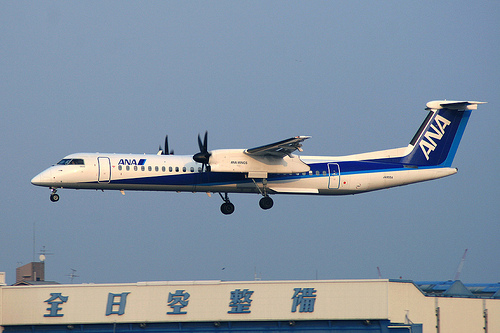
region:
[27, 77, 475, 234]
Large plane flying in the air.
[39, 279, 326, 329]
Asian letters on the building.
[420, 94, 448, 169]
The logo of the plane.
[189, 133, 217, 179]
Black propeller of a plane.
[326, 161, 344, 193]
Door of the airplane.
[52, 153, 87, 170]
Cockpit window of the airplane.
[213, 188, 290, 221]
Landing gear of the airplane.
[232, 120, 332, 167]
The wing of an airplane.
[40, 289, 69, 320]
letter is asian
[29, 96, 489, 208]
plane is in the air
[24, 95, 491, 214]
plane has propellers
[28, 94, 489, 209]
plane has landing gear down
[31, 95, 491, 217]
plane is ANA brand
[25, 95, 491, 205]
plane is white and blue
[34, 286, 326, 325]
letters are blue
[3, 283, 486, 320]
building is below the plane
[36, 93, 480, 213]
plane is above the building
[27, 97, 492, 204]
plane has two doors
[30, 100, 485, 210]
Blue and white airplane.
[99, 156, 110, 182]
Front door on the airplane.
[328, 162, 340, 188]
Back door on the airplane.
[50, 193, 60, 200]
Front tire on the airplane.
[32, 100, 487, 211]
Airplane is flying over a building.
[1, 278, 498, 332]
Blue and white building below airplane.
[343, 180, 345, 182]
Red spot behind back airplane door.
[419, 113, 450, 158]
ANA logo on tail of airplane.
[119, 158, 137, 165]
ANA logo near front door of airplane.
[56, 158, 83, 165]
Front windows of airplane.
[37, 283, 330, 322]
Blue written foreign language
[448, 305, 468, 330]
Clean crisp white wall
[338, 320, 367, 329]
Blue colored metal walls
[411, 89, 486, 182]
An ANA airline plane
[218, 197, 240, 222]
Small steady black wheels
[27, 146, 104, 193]
Front streamlined plane exterior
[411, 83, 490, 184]
Blue and white colored tail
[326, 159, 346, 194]
A closed plane door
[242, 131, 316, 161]
Big steady plane wing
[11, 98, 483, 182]
blue and white plane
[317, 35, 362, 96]
white clouds in blue sky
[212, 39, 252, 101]
white clouds in blue sky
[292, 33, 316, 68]
white clouds in blue sky